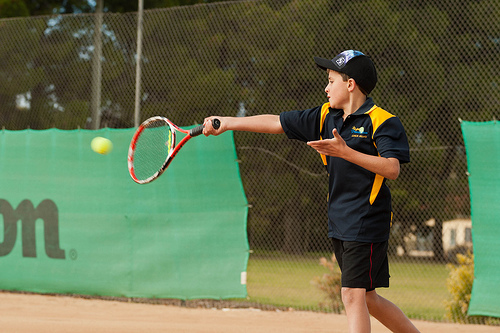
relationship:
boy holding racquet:
[194, 39, 425, 332] [121, 114, 201, 185]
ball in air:
[88, 128, 118, 154] [4, 4, 226, 332]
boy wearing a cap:
[194, 39, 425, 332] [315, 47, 385, 93]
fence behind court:
[8, 14, 499, 316] [4, 4, 499, 331]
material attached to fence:
[4, 126, 500, 314] [8, 14, 499, 316]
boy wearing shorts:
[194, 39, 425, 332] [319, 201, 397, 295]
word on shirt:
[346, 125, 374, 144] [276, 105, 422, 245]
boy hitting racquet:
[194, 39, 425, 332] [121, 114, 201, 185]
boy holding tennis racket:
[194, 39, 425, 332] [123, 110, 207, 190]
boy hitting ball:
[194, 39, 425, 332] [88, 128, 118, 154]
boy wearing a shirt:
[194, 39, 425, 332] [276, 105, 422, 245]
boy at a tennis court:
[194, 39, 425, 332] [4, 4, 499, 331]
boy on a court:
[194, 39, 425, 332] [4, 4, 499, 331]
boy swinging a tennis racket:
[194, 39, 425, 332] [123, 110, 207, 190]